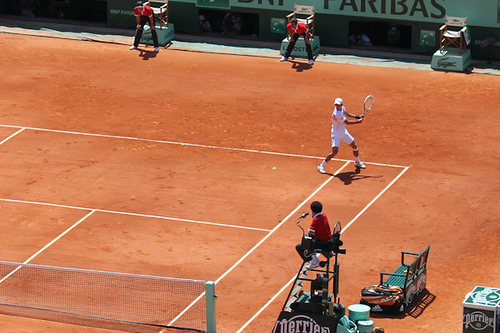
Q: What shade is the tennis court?
A: Red.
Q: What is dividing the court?
A: Net.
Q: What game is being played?
A: Tennis.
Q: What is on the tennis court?
A: White lines.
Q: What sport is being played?
A: Tennis.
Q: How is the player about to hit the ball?
A: Backhand.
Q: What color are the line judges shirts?
A: Red.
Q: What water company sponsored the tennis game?
A: Perrier.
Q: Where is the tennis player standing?
A: Court.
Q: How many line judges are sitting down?
A: One.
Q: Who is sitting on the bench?
A: No one.